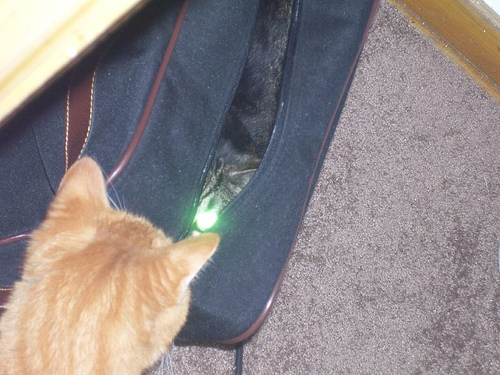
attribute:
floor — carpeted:
[388, 22, 495, 296]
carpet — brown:
[401, 149, 441, 211]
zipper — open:
[178, 0, 306, 242]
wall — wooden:
[397, 0, 498, 87]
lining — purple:
[53, 5, 191, 182]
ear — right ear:
[155, 227, 227, 299]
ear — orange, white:
[44, 155, 107, 220]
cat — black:
[199, 10, 303, 207]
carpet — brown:
[141, 0, 498, 374]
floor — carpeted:
[94, 0, 498, 374]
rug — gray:
[394, 211, 479, 339]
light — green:
[182, 194, 233, 233]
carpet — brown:
[252, 5, 498, 371]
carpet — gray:
[95, 5, 496, 370]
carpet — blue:
[19, 3, 494, 373]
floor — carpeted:
[376, 160, 451, 232]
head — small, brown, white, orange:
[12, 150, 223, 374]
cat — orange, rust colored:
[6, 150, 226, 374]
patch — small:
[386, 146, 498, 270]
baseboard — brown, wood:
[426, 14, 494, 74]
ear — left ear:
[56, 164, 104, 206]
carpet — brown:
[217, 0, 497, 374]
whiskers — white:
[104, 162, 124, 207]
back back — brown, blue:
[0, 0, 391, 356]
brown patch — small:
[350, 87, 375, 119]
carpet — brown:
[349, 32, 489, 366]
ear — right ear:
[46, 155, 109, 211]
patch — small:
[290, 283, 340, 329]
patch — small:
[333, 151, 413, 203]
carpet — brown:
[355, 134, 438, 327]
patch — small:
[366, 70, 446, 149]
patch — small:
[364, 60, 438, 154]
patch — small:
[388, 108, 451, 185]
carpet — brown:
[342, 133, 480, 340]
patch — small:
[379, 85, 481, 142]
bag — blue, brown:
[0, 0, 379, 344]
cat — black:
[188, 0, 290, 232]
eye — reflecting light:
[197, 209, 218, 229]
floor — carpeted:
[147, 4, 499, 374]